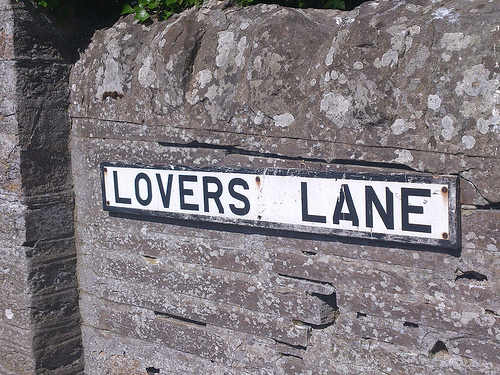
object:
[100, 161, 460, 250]
sign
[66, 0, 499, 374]
wall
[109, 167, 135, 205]
l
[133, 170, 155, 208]
o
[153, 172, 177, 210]
v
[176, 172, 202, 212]
e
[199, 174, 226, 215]
r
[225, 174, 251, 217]
s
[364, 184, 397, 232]
n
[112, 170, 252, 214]
letters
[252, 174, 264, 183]
bolts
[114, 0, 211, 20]
trees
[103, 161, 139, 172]
edge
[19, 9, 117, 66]
shadow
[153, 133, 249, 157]
crack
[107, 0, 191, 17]
leaves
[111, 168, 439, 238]
lovers lane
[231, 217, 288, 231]
paint